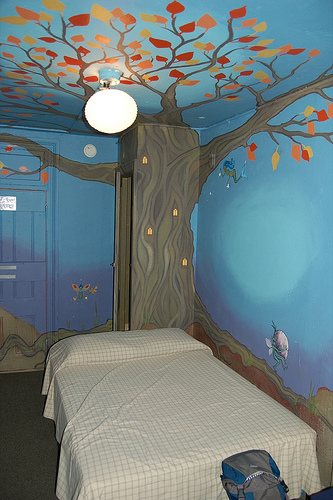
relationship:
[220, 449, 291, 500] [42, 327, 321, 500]
backpack leaning against bed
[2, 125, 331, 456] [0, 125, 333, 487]
painted mural on wall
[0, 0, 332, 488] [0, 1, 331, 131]
painted mural painted on ceiling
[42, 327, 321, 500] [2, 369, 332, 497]
bed resting on floor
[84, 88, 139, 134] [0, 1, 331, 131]
light hanging from ceiling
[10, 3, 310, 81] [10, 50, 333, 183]
leaves attached to branches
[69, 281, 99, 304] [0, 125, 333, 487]
butterfly painted on wall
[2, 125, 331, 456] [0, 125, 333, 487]
painted mural painted on wall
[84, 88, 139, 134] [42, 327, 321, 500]
light above bed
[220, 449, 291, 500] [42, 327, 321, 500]
backpack in front of bed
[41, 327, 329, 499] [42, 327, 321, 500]
sheet on top of bed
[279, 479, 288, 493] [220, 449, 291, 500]
left snap attached to backpack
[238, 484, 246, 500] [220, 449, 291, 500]
right snap attached to backpack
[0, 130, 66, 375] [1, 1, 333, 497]
room door inside room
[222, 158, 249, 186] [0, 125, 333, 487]
mermaid painted on wall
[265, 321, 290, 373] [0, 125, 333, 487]
alien painted on wall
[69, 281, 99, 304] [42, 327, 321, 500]
butterfly above bed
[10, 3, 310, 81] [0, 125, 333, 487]
leaves painted on wall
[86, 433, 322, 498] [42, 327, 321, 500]
edge of bed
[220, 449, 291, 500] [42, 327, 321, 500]
backpack next to bed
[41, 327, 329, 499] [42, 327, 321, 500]
bedspread covering bed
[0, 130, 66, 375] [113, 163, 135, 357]
room door left of closet door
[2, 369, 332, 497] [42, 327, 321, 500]
floor beneath bed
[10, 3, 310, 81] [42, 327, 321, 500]
leaves above bed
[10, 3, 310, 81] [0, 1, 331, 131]
leaves painted on ceiling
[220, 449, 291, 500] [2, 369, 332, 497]
backpack on top of floor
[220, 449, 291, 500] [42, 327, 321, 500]
backpack against bed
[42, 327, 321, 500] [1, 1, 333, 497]
bed inside room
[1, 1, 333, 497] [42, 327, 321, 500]
room contains bed